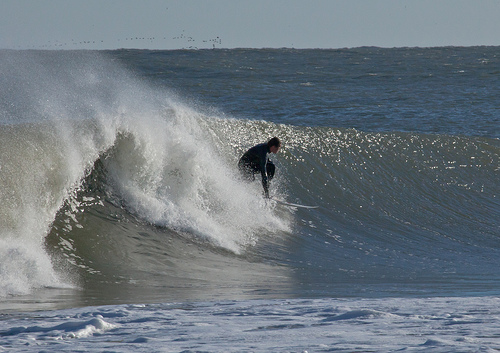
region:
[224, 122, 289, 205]
a surfer on a wave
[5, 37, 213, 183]
splash above the wave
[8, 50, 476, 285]
a wave is rolling in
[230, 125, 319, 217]
man in on surfboard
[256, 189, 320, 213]
a white surfboard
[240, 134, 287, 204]
man is crouched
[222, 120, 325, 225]
surfer holds surfboard with right hand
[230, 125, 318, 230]
surfer going to the right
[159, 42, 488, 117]
part of the sea is calm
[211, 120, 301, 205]
surfer has black cloths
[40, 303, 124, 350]
ripples in the water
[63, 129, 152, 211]
ripples in the water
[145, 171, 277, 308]
ripples in the water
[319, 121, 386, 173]
ripples in the water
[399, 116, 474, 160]
ripples in the water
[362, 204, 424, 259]
ripples in the water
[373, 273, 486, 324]
ripples in the water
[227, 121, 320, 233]
PErson in the water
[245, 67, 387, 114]
ripples in the water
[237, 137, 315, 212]
a man surfing like a pro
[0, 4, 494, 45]
a completly cloudy sky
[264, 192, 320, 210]
the surf board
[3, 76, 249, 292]
a foamy wave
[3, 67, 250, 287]
a large wave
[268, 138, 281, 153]
the head of the surfer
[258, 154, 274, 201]
one arm of the man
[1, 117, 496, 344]
a man enjoying the wave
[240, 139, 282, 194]
maneuvering between the wave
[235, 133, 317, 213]
a surfer practicing surfing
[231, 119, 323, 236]
A riding the surf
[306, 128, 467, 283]
A large wave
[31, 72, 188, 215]
White foam on the wave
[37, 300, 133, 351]
White foam on the water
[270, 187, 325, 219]
Surfer on white surfboard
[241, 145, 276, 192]
A black surfing outfit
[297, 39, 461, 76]
Waves in the distance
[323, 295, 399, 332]
A bump of foam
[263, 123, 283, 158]
A surfer with brown hair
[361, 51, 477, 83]
Little choppy waves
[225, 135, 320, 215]
a man surfing on water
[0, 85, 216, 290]
a white wave of water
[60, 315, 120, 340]
a small foamy wave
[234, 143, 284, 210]
a man in a black wet suite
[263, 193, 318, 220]
a white surf board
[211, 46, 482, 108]
crystal blue waters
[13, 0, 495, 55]
crystal blue skys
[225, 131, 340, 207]
a man leaning down on his board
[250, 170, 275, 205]
a mans hand on the board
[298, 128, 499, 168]
reflection of light on the water